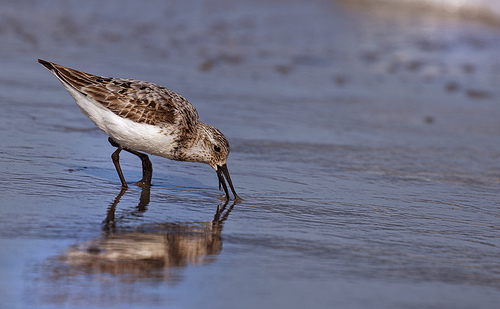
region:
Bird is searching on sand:
[27, 48, 254, 218]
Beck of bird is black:
[207, 159, 247, 207]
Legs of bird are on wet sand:
[93, 137, 159, 204]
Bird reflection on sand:
[36, 210, 238, 293]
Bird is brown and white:
[25, 48, 259, 217]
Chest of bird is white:
[59, 93, 174, 170]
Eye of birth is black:
[206, 139, 224, 156]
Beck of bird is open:
[209, 156, 249, 213]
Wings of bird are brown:
[39, 48, 210, 124]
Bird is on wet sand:
[9, 31, 296, 279]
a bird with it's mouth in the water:
[58, 39, 308, 274]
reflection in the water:
[68, 226, 308, 287]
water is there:
[318, 175, 433, 285]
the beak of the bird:
[215, 176, 253, 203]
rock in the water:
[361, 7, 498, 117]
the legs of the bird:
[104, 148, 177, 185]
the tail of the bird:
[38, 43, 102, 101]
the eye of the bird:
[208, 138, 227, 156]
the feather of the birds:
[106, 76, 167, 123]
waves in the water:
[265, 121, 362, 211]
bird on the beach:
[41, 43, 254, 216]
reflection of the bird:
[87, 204, 204, 307]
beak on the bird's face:
[207, 159, 251, 201]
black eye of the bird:
[206, 134, 224, 159]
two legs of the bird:
[91, 154, 170, 203]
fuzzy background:
[309, 14, 451, 104]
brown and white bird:
[66, 56, 261, 211]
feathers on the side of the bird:
[98, 83, 184, 152]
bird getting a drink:
[10, 11, 320, 268]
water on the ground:
[251, 162, 376, 269]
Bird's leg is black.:
[108, 150, 130, 188]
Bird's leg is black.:
[133, 146, 183, 221]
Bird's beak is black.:
[213, 162, 242, 204]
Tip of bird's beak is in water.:
[208, 169, 266, 240]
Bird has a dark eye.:
[205, 145, 220, 157]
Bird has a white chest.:
[86, 105, 176, 167]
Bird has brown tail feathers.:
[31, 57, 118, 91]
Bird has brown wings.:
[104, 78, 161, 96]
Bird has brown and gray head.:
[156, 97, 236, 156]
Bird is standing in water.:
[51, 162, 303, 247]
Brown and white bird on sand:
[19, 48, 261, 231]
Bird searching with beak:
[186, 116, 262, 214]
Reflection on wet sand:
[39, 205, 234, 290]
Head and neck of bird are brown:
[174, 108, 233, 171]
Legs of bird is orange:
[99, 149, 161, 203]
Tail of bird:
[26, 51, 83, 87]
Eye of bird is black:
[210, 137, 225, 157]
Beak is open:
[211, 159, 241, 206]